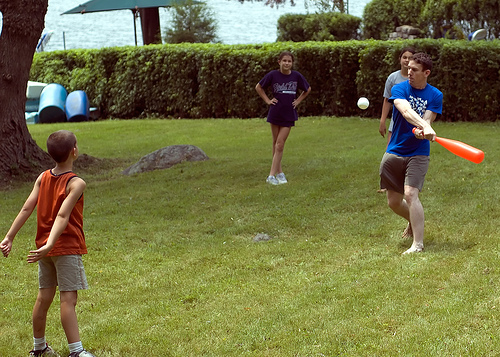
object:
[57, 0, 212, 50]
umbrella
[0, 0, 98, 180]
tree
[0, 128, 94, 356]
person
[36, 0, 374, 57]
water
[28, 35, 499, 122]
hedge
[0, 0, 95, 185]
tree trunk